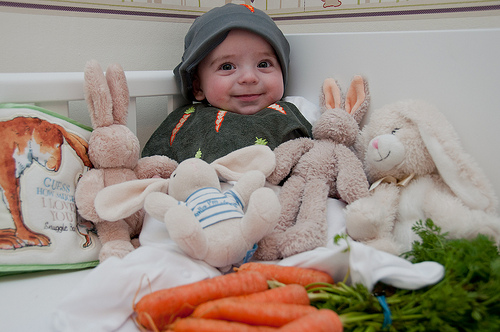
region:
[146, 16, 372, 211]
a baby and som rabbits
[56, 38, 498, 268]
four stuffed bunny rabbits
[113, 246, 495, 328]
a bunch of carrots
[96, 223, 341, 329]
some raw orange carrots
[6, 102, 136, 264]
a bunny on a blanket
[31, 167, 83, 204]
blue letters on blanket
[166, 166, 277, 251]
blue and white shirt on bunny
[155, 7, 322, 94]
a gray hat on head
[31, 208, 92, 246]
black letters on blanket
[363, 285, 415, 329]
blue rubber band on carrots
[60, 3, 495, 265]
this baby has many stuffed animals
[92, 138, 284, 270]
this stuffed bunny is wearing a blue striped shirt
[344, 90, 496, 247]
this stuffed bunny has a sweet smile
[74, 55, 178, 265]
this stuffed bunny is a faceless enigma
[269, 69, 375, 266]
another stuffed bunny bereft of identity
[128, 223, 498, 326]
a bunch of real carrots for the stuffed bunnies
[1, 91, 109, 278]
a picture of a bunny on some craft item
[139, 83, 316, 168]
baby wearing carrots on his clothing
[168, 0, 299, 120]
baby is wearing a carrot cap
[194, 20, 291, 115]
baby looks kind of sort of pleased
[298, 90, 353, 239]
a stuffed animal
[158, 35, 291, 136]
a child laying on a bed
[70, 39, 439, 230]
a kid laying with stuffed animals around him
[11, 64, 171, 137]
the white headboard on the bed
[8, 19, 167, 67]
the wall behind the bed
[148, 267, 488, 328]
carrots on the bed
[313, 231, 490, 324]
the leaves on the carrots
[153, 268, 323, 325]
orange carrots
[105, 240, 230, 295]
blankets on the bed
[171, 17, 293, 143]
a kid with a hat on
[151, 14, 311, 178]
a baby on a bed smiling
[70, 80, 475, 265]
several stuffed bunnies on a bed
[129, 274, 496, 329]
orange carrots sitting on a bed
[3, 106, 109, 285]
a knitted baby's bib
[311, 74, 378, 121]
the ears of a stuffed rabbit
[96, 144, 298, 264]
a white stuffed rabbit with big ears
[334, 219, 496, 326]
the green tops of carrots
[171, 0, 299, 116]
a baby's smiling face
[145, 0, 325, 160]
a baby wearing a carrot costume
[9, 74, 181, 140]
the headboard of a bed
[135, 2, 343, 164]
baby sitting in crib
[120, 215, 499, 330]
full carrots with green tops in crib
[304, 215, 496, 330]
long green leafy carrot tops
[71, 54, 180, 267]
pink stuffed rabbit in crib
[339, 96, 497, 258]
white and tan rabbit in crib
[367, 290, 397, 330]
blue tie around green carrot tops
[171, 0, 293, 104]
grey and orange hat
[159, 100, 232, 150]
carrots on grey bibs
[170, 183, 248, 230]
blue and white striped shirt on stuffed animal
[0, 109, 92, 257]
orange and white rabbit on green and white bib